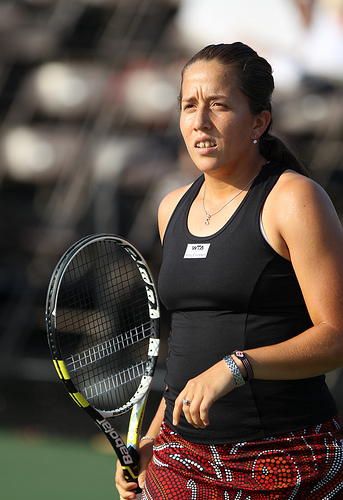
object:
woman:
[46, 42, 343, 499]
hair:
[176, 41, 310, 178]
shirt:
[157, 163, 339, 444]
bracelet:
[231, 348, 255, 381]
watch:
[231, 351, 255, 384]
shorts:
[140, 413, 343, 499]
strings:
[69, 267, 138, 374]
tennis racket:
[44, 235, 163, 497]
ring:
[183, 399, 191, 406]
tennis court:
[0, 422, 145, 499]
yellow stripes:
[52, 359, 71, 380]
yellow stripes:
[68, 392, 90, 408]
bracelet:
[223, 355, 246, 387]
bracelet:
[141, 436, 156, 441]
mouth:
[196, 141, 217, 149]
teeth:
[197, 142, 215, 147]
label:
[183, 243, 211, 259]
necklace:
[201, 174, 259, 226]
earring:
[253, 139, 257, 144]